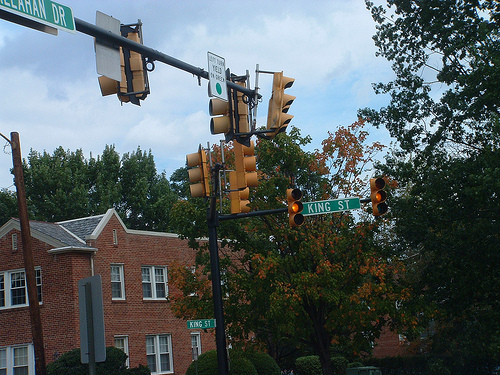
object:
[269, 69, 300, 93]
traffic light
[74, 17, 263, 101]
pole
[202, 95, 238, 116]
traffic light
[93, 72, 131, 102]
traffic light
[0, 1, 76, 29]
street sign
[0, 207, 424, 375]
building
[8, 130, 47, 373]
electrical pole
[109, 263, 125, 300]
window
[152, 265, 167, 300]
window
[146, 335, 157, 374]
window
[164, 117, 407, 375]
tree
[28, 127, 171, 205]
leaves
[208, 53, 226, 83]
writing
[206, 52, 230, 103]
sign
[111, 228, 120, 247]
window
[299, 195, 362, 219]
sign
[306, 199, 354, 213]
king st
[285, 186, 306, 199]
traffic light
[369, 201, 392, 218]
traffic light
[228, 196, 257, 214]
traffic light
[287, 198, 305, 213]
traffic light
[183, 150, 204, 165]
traffic light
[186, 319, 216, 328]
king st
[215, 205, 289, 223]
pole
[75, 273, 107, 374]
sign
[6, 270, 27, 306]
window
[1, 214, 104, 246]
roof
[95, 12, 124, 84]
sign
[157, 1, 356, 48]
sky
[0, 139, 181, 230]
trees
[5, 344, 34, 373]
frame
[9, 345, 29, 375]
window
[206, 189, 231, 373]
post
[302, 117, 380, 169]
leaves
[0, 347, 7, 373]
window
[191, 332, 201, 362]
window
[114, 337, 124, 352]
window